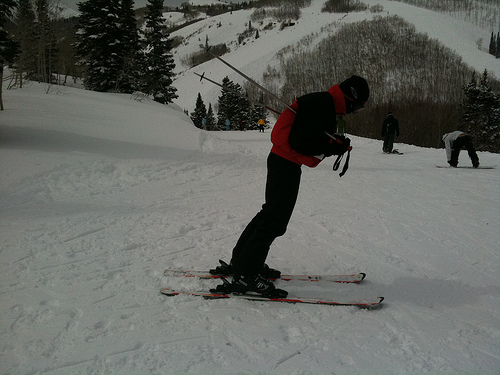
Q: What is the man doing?
A: Skiing.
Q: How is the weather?
A: Clear.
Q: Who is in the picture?
A: A man.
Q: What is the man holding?
A: Poles.